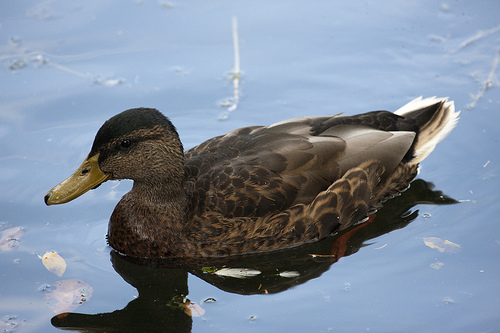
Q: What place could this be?
A: It is a lake.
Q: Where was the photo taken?
A: It was taken at the lake.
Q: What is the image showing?
A: It is showing a lake.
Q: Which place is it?
A: It is a lake.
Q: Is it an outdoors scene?
A: Yes, it is outdoors.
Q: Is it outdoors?
A: Yes, it is outdoors.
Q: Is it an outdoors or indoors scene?
A: It is outdoors.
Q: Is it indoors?
A: No, it is outdoors.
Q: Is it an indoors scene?
A: No, it is outdoors.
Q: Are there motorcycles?
A: No, there are no motorcycles.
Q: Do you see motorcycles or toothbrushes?
A: No, there are no motorcycles or toothbrushes.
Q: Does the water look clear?
A: Yes, the water is clear.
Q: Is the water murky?
A: No, the water is clear.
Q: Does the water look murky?
A: No, the water is clear.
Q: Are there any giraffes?
A: No, there are no giraffes.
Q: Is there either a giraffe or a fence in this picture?
A: No, there are no giraffes or fences.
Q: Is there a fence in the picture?
A: No, there are no fences.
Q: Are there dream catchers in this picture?
A: No, there are no dream catchers.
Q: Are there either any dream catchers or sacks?
A: No, there are no dream catchers or sacks.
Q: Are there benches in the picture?
A: No, there are no benches.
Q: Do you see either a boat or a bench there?
A: No, there are no benches or boats.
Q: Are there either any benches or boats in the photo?
A: No, there are no benches or boats.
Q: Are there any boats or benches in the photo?
A: No, there are no benches or boats.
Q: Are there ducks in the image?
A: Yes, there is a duck.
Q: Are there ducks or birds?
A: Yes, there is a duck.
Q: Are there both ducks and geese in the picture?
A: No, there is a duck but no geese.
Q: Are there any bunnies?
A: No, there are no bunnies.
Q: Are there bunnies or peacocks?
A: No, there are no bunnies or peacocks.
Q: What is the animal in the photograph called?
A: The animal is a duck.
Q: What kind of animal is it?
A: The animal is a duck.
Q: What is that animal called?
A: This is a duck.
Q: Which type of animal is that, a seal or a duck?
A: This is a duck.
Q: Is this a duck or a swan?
A: This is a duck.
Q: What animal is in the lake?
A: The duck is in the lake.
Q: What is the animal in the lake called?
A: The animal is a duck.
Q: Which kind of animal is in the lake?
A: The animal is a duck.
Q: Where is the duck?
A: The duck is in the lake.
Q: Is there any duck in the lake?
A: Yes, there is a duck in the lake.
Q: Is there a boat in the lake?
A: No, there is a duck in the lake.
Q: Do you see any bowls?
A: No, there are no bowls.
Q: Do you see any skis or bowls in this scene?
A: No, there are no bowls or skis.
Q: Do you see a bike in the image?
A: No, there are no bikes.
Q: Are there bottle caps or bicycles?
A: No, there are no bicycles or bottle caps.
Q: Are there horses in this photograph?
A: No, there are no horses.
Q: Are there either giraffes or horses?
A: No, there are no horses or giraffes.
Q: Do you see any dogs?
A: No, there are no dogs.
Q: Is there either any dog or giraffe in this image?
A: No, there are no dogs or giraffes.